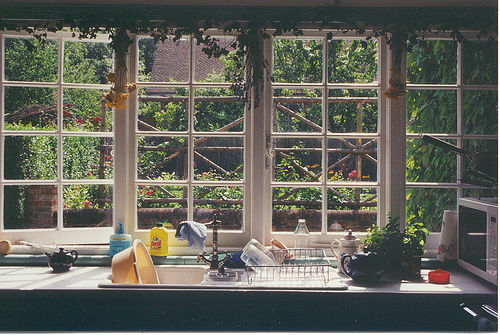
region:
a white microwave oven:
[454, 201, 499, 286]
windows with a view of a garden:
[0, 18, 497, 231]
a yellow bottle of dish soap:
[146, 222, 171, 257]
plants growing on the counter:
[354, 218, 441, 288]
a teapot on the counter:
[340, 245, 392, 285]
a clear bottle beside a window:
[291, 218, 315, 257]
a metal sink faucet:
[173, 208, 230, 271]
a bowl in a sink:
[110, 243, 181, 287]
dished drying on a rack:
[242, 235, 328, 285]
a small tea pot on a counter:
[40, 243, 83, 276]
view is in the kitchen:
[56, 64, 364, 199]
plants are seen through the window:
[69, 36, 374, 186]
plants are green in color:
[46, 16, 388, 196]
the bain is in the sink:
[109, 237, 186, 311]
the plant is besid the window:
[371, 221, 421, 280]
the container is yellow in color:
[137, 219, 187, 253]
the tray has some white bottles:
[253, 239, 326, 295]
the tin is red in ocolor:
[428, 262, 454, 279]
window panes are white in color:
[23, 86, 189, 218]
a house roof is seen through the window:
[155, 34, 237, 124]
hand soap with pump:
[97, 210, 134, 261]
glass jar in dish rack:
[239, 242, 276, 276]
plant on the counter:
[366, 205, 423, 262]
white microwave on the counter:
[452, 186, 491, 268]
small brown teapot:
[39, 242, 81, 268]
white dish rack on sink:
[244, 240, 332, 279]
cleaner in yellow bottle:
[147, 220, 182, 261]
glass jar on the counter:
[289, 214, 310, 251]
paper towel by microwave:
[431, 202, 456, 262]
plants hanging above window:
[5, 10, 495, 50]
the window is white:
[6, 8, 479, 258]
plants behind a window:
[1, 19, 473, 242]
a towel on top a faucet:
[168, 206, 224, 266]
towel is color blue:
[176, 210, 208, 250]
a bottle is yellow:
[146, 216, 173, 259]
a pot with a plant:
[362, 207, 433, 279]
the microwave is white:
[449, 188, 499, 290]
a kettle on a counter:
[39, 244, 83, 275]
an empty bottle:
[289, 214, 314, 256]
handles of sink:
[194, 247, 239, 270]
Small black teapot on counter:
[44, 246, 79, 273]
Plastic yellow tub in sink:
[111, 238, 161, 285]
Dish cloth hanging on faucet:
[172, 219, 207, 249]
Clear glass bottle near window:
[291, 217, 309, 260]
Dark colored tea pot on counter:
[339, 244, 394, 287]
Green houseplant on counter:
[361, 209, 428, 283]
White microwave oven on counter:
[454, 194, 499, 288]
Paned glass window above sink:
[128, 94, 260, 247]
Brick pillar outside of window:
[21, 183, 59, 228]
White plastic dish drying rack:
[246, 244, 332, 286]